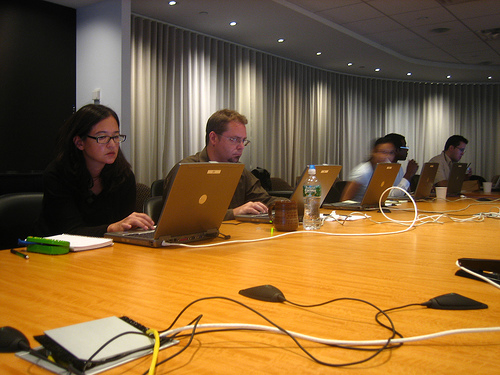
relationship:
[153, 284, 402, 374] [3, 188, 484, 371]
cord coming through desk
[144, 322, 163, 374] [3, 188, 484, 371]
cord from desk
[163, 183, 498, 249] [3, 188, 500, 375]
cord coming out of desk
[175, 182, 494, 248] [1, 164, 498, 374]
ethernet cord coming out of desk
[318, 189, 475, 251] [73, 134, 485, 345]
cord coming out of desk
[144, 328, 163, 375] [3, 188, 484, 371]
cord coming out of desk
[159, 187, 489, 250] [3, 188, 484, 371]
ethernet cord coming out of desk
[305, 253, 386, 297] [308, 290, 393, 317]
part of a wire